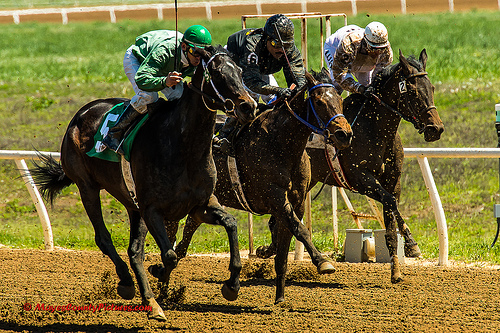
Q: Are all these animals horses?
A: Yes, all the animals are horses.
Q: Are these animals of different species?
A: No, all the animals are horses.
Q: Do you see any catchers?
A: No, there are no catchers.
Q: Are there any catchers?
A: No, there are no catchers.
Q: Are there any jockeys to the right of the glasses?
A: Yes, there is a jockey to the right of the glasses.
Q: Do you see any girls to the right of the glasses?
A: No, there is a jockey to the right of the glasses.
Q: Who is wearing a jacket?
A: The jockey is wearing a jacket.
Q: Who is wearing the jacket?
A: The jockey is wearing a jacket.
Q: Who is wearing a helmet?
A: The jockey is wearing a helmet.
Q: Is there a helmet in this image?
A: Yes, there is a helmet.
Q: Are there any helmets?
A: Yes, there is a helmet.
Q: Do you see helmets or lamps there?
A: Yes, there is a helmet.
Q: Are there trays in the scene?
A: No, there are no trays.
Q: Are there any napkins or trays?
A: No, there are no trays or napkins.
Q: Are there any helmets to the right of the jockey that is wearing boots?
A: Yes, there is a helmet to the right of the jockey.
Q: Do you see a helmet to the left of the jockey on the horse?
A: No, the helmet is to the right of the jockey.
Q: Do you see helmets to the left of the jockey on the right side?
A: Yes, there is a helmet to the left of the jockey.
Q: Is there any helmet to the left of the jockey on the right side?
A: Yes, there is a helmet to the left of the jockey.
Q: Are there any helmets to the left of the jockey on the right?
A: Yes, there is a helmet to the left of the jockey.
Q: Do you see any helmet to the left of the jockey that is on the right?
A: Yes, there is a helmet to the left of the jockey.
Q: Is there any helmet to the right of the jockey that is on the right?
A: No, the helmet is to the left of the jockey.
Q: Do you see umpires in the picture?
A: No, there are no umpires.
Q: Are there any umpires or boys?
A: No, there are no umpires or boys.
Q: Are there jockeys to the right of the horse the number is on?
A: Yes, there is a jockey to the right of the horse.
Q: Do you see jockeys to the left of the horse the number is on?
A: No, the jockey is to the right of the horse.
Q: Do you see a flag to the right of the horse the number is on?
A: No, there is a jockey to the right of the horse.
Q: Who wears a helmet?
A: The jockey wears a helmet.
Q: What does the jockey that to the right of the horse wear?
A: The jockey wears a helmet.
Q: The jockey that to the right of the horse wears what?
A: The jockey wears a helmet.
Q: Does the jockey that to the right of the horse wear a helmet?
A: Yes, the jockey wears a helmet.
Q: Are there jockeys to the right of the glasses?
A: Yes, there is a jockey to the right of the glasses.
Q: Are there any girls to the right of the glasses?
A: No, there is a jockey to the right of the glasses.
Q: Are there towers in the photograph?
A: No, there are no towers.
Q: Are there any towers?
A: No, there are no towers.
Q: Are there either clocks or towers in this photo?
A: No, there are no towers or clocks.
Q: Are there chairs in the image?
A: No, there are no chairs.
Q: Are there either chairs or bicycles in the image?
A: No, there are no chairs or bicycles.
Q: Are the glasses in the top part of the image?
A: Yes, the glasses are in the top of the image.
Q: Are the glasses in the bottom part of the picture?
A: No, the glasses are in the top of the image.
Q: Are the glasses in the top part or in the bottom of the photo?
A: The glasses are in the top of the image.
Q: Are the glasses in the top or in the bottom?
A: The glasses are in the top of the image.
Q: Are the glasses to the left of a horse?
A: Yes, the glasses are to the left of a horse.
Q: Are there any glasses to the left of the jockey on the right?
A: Yes, there are glasses to the left of the jockey.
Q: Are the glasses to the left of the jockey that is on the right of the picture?
A: Yes, the glasses are to the left of the jockey.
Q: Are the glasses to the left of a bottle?
A: No, the glasses are to the left of the jockey.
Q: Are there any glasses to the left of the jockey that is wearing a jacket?
A: Yes, there are glasses to the left of the jockey.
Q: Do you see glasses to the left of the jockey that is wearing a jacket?
A: Yes, there are glasses to the left of the jockey.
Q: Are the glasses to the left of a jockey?
A: Yes, the glasses are to the left of a jockey.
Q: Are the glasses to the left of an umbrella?
A: No, the glasses are to the left of a jockey.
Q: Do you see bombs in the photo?
A: No, there are no bombs.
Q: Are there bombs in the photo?
A: No, there are no bombs.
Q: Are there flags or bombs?
A: No, there are no bombs or flags.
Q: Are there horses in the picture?
A: Yes, there is a horse.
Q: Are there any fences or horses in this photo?
A: Yes, there is a horse.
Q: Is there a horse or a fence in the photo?
A: Yes, there is a horse.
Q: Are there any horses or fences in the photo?
A: Yes, there is a horse.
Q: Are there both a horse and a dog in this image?
A: No, there is a horse but no dogs.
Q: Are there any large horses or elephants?
A: Yes, there is a large horse.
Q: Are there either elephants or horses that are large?
A: Yes, the horse is large.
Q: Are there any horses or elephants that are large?
A: Yes, the horse is large.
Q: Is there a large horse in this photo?
A: Yes, there is a large horse.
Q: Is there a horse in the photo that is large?
A: Yes, there is a horse that is large.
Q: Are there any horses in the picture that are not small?
A: Yes, there is a large horse.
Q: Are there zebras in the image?
A: No, there are no zebras.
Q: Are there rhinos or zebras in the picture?
A: No, there are no zebras or rhinos.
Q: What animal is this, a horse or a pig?
A: This is a horse.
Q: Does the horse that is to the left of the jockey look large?
A: Yes, the horse is large.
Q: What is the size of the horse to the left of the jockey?
A: The horse is large.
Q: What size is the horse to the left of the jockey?
A: The horse is large.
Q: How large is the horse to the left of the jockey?
A: The horse is large.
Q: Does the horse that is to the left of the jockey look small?
A: No, the horse is large.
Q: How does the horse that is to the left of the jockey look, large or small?
A: The horse is large.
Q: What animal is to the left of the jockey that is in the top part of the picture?
A: The animal is a horse.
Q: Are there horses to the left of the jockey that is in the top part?
A: Yes, there is a horse to the left of the jockey.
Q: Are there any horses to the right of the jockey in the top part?
A: No, the horse is to the left of the jockey.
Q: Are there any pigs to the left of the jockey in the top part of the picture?
A: No, there is a horse to the left of the jockey.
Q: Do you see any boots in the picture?
A: Yes, there are boots.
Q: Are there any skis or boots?
A: Yes, there are boots.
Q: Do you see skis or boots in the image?
A: Yes, there are boots.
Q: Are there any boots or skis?
A: Yes, there are boots.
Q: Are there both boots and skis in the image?
A: No, there are boots but no skis.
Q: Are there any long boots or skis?
A: Yes, there are long boots.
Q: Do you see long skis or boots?
A: Yes, there are long boots.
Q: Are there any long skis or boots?
A: Yes, there are long boots.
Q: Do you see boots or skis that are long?
A: Yes, the boots are long.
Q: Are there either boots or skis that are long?
A: Yes, the boots are long.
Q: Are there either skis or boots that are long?
A: Yes, the boots are long.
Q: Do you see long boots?
A: Yes, there are long boots.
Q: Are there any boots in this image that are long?
A: Yes, there are boots that are long.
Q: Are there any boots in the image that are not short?
A: Yes, there are long boots.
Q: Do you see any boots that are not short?
A: Yes, there are long boots.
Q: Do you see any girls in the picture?
A: No, there are no girls.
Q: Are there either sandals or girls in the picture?
A: No, there are no girls or sandals.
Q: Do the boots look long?
A: Yes, the boots are long.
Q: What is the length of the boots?
A: The boots are long.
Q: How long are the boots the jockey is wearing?
A: The boots are long.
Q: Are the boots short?
A: No, the boots are long.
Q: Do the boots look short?
A: No, the boots are long.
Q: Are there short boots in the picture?
A: No, there are boots but they are long.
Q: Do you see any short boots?
A: No, there are boots but they are long.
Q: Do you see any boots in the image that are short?
A: No, there are boots but they are long.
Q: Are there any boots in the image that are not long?
A: No, there are boots but they are long.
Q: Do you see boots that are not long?
A: No, there are boots but they are long.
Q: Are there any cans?
A: No, there are no cans.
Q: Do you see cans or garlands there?
A: No, there are no cans or garlands.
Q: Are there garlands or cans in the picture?
A: No, there are no cans or garlands.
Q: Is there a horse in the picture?
A: Yes, there is a horse.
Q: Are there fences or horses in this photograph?
A: Yes, there is a horse.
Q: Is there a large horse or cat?
A: Yes, there is a large horse.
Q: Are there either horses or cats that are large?
A: Yes, the horse is large.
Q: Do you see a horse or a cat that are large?
A: Yes, the horse is large.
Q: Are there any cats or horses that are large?
A: Yes, the horse is large.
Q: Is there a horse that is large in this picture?
A: Yes, there is a large horse.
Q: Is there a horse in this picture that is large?
A: Yes, there is a horse that is large.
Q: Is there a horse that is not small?
A: Yes, there is a large horse.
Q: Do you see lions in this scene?
A: No, there are no lions.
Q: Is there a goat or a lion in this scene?
A: No, there are no lions or goats.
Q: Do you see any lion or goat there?
A: No, there are no lions or goats.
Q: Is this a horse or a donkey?
A: This is a horse.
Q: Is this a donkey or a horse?
A: This is a horse.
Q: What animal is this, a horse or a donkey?
A: This is a horse.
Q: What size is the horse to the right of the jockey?
A: The horse is large.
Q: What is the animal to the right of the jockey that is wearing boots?
A: The animal is a horse.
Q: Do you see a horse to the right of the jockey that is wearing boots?
A: Yes, there is a horse to the right of the jockey.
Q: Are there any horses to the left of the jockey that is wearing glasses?
A: No, the horse is to the right of the jockey.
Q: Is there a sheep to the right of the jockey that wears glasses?
A: No, there is a horse to the right of the jockey.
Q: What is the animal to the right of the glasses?
A: The animal is a horse.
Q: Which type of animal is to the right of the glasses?
A: The animal is a horse.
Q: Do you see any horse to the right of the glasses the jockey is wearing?
A: Yes, there is a horse to the right of the glasses.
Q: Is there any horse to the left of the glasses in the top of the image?
A: No, the horse is to the right of the glasses.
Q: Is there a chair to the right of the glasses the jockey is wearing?
A: No, there is a horse to the right of the glasses.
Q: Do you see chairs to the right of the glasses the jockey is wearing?
A: No, there is a horse to the right of the glasses.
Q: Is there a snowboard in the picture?
A: No, there are no snowboards.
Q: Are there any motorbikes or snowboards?
A: No, there are no snowboards or motorbikes.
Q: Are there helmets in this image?
A: Yes, there is a helmet.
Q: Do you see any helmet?
A: Yes, there is a helmet.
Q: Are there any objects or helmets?
A: Yes, there is a helmet.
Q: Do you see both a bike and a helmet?
A: No, there is a helmet but no bikes.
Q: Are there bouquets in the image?
A: No, there are no bouquets.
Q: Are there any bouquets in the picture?
A: No, there are no bouquets.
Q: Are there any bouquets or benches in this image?
A: No, there are no bouquets or benches.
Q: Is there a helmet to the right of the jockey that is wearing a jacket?
A: Yes, there is a helmet to the right of the jockey.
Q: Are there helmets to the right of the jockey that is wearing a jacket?
A: Yes, there is a helmet to the right of the jockey.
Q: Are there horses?
A: Yes, there is a horse.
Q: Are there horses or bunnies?
A: Yes, there is a horse.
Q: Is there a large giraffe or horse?
A: Yes, there is a large horse.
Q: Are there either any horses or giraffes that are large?
A: Yes, the horse is large.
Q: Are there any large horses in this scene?
A: Yes, there is a large horse.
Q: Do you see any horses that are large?
A: Yes, there is a large horse.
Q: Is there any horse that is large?
A: Yes, there is a horse that is large.